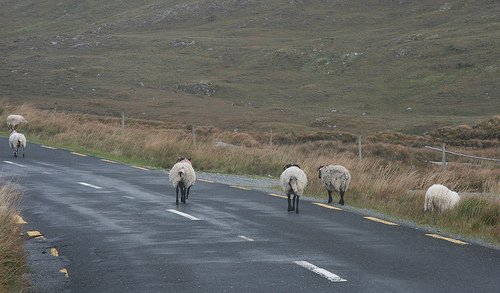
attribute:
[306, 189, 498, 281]
lines — Yellow 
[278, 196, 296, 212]
leg — black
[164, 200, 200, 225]
stripe — yellow 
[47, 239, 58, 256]
stripe — white 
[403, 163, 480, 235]
sheep — white 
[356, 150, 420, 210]
grass — tall 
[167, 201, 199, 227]
line — White 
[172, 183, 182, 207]
leg — black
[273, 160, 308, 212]
sheep — white , black 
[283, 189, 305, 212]
black legs — long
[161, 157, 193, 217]
sheep — white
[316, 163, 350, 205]
sheep — black , white 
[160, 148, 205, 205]
sheep — black, white, walking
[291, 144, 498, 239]
tall grass — dry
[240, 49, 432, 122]
grass — green 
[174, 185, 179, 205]
leg — black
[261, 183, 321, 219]
legs — black 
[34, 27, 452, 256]
field — large